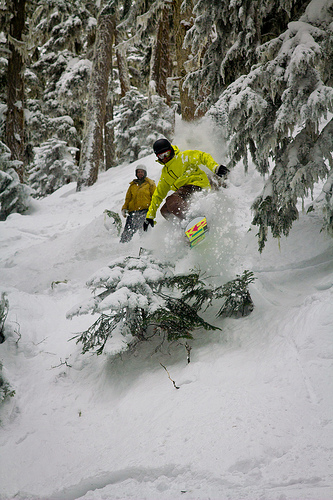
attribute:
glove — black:
[217, 163, 232, 179]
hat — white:
[129, 162, 152, 173]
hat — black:
[153, 137, 174, 162]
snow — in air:
[150, 202, 239, 279]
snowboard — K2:
[183, 213, 209, 251]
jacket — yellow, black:
[139, 154, 234, 227]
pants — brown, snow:
[159, 183, 201, 228]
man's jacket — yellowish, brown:
[123, 168, 154, 216]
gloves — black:
[216, 162, 225, 180]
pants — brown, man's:
[157, 183, 198, 226]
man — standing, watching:
[119, 161, 156, 243]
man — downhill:
[142, 138, 230, 231]